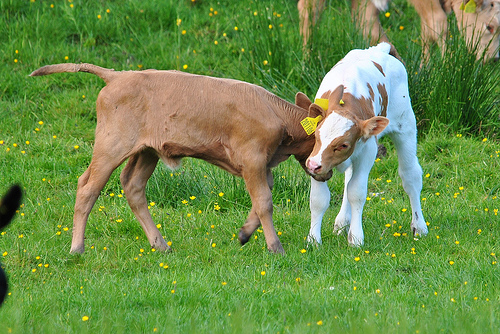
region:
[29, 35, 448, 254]
two baby cows playing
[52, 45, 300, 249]
a brown cow in the grass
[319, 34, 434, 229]
a brown and white cow in the grass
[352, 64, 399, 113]
a white cow with brown spots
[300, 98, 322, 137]
a yellow tag on a cow's ear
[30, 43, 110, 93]
the brown tail of a cow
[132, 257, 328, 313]
yellow flowers in the green grass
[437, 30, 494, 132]
tall green grass blades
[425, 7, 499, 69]
a cow eating grass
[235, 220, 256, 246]
the hoof of a cow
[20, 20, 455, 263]
two calves playing together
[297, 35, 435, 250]
white calf with brown markings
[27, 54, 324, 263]
brown calf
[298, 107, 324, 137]
yellow tag on ear of white calf with brown markings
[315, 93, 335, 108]
yellow tag on brown calve's ear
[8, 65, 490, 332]
grass pasture calves are playing in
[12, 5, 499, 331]
tiny yellow flowers in the grass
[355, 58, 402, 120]
brown markings on side of white calf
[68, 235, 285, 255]
hooves of brown calf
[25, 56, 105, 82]
tail of brown calf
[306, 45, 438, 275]
this is a calf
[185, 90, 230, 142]
the calf is brown in color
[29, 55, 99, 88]
this is the tail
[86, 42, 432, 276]
the calf are two in number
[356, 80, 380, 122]
the calf is white and brown in color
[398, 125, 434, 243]
this is the leg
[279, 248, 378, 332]
this is a grass area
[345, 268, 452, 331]
the grass is green in color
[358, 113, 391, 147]
this is the ear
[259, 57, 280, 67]
this is a small flower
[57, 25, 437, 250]
two cows close together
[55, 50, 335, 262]
cow with brown body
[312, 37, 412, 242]
brown and white cow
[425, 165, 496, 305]
thick green grass near cows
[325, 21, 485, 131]
tall green grass behind cows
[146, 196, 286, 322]
yellow dandelions in field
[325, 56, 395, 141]
brown spots on cow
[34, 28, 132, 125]
cow has brown tail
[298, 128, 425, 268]
cow has white legs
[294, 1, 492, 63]
brown cow eating grass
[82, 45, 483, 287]
two cows near each other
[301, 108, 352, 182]
white stripe on cow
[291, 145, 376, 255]
cow has white legs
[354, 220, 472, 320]
green grass around cows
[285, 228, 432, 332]
yellow dandelions on grass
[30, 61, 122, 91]
cow has brown tail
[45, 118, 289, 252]
cow has brown legs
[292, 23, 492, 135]
tall thick green grass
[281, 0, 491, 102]
cow is eating grass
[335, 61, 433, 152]
brown spots on cow